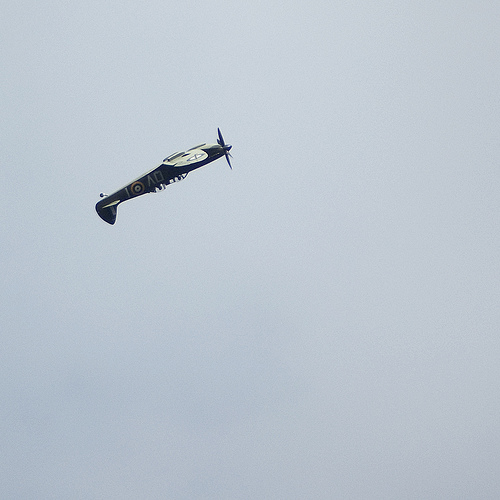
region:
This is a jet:
[80, 122, 271, 243]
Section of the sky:
[10, 5, 97, 95]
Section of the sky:
[20, 83, 110, 163]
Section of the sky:
[18, 246, 122, 381]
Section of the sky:
[12, 389, 129, 499]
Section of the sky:
[178, 233, 283, 374]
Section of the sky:
[245, 318, 335, 465]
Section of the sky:
[341, 361, 433, 496]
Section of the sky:
[358, 212, 486, 337]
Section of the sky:
[370, 86, 490, 243]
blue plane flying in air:
[77, 125, 247, 230]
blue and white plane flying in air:
[92, 123, 234, 222]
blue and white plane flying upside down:
[84, 123, 246, 228]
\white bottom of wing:
[170, 146, 207, 166]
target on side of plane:
[131, 182, 145, 192]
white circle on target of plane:
[135, 183, 139, 190]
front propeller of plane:
[207, 125, 237, 173]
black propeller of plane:
[208, 128, 235, 170]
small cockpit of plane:
[160, 168, 200, 189]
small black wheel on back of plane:
[95, 188, 108, 199]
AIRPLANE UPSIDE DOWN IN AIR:
[102, 93, 230, 228]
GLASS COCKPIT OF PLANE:
[141, 170, 198, 197]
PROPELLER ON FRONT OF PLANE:
[208, 116, 250, 186]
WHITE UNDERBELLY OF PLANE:
[161, 130, 244, 178]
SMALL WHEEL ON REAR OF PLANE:
[65, 179, 118, 209]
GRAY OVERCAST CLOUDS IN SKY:
[40, 284, 311, 491]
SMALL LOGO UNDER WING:
[186, 141, 221, 171]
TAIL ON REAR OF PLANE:
[104, 187, 134, 226]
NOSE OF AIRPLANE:
[201, 140, 252, 179]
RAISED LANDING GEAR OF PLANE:
[149, 134, 202, 169]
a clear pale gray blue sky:
[3, 0, 496, 497]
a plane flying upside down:
[92, 125, 235, 231]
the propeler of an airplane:
[215, 128, 238, 170]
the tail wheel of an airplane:
[96, 191, 106, 197]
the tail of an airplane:
[93, 205, 118, 226]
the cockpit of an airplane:
[164, 170, 191, 186]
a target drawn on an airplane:
[130, 178, 146, 199]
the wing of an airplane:
[158, 143, 209, 169]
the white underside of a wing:
[164, 148, 205, 163]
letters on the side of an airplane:
[144, 166, 166, 191]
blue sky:
[0, 0, 497, 499]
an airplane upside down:
[95, 128, 233, 223]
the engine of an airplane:
[216, 128, 235, 169]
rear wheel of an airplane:
[99, 192, 107, 196]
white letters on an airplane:
[145, 170, 164, 186]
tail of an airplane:
[96, 196, 121, 223]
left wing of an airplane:
[161, 149, 206, 164]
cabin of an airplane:
[153, 173, 190, 190]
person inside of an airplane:
[156, 184, 163, 189]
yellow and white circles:
[129, 182, 145, 194]